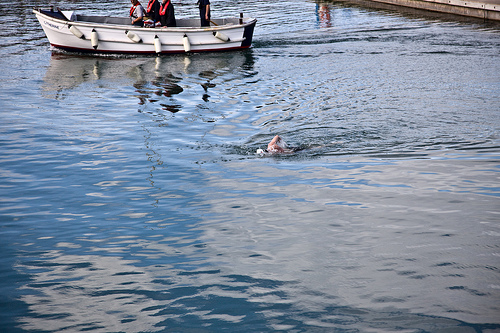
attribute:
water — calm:
[320, 113, 486, 329]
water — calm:
[26, 111, 131, 264]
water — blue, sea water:
[164, 188, 471, 328]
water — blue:
[218, 196, 352, 283]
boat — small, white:
[31, 9, 256, 61]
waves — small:
[43, 188, 490, 321]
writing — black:
[41, 20, 59, 30]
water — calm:
[100, 105, 452, 250]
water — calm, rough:
[1, 2, 499, 331]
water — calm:
[324, 56, 491, 178]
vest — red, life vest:
[135, 1, 182, 26]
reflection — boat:
[44, 48, 255, 214]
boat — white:
[24, 8, 262, 58]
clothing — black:
[143, 8, 178, 27]